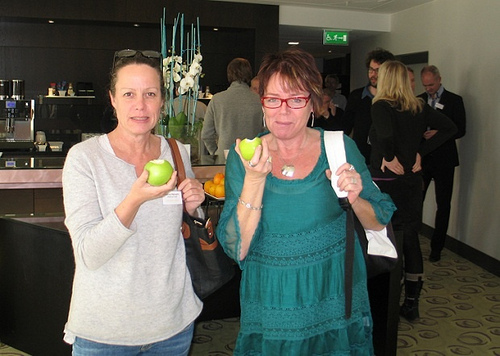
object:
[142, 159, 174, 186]
apples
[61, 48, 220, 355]
lady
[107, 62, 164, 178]
light skin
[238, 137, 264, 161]
apple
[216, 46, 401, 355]
woman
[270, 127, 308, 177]
necklace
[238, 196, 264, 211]
wristband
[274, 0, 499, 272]
wall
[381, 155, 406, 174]
hands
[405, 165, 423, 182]
hips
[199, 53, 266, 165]
man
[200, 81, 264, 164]
sweater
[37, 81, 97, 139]
coffee maker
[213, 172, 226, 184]
oranges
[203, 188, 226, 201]
bowl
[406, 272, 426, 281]
socks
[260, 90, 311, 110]
glasses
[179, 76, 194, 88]
flowers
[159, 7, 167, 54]
sticks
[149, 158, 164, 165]
bites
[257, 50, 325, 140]
head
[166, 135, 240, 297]
bag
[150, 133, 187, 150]
shoulder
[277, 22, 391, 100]
hall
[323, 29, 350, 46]
sign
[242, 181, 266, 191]
wrist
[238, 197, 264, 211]
bracelet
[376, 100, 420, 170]
back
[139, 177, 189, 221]
chest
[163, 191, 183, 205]
tag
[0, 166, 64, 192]
counter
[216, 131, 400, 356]
dress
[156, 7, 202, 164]
floral arrangement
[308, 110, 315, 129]
earrings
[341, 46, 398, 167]
man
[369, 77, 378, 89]
beard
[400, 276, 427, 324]
boot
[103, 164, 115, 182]
white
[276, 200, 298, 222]
green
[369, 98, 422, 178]
suit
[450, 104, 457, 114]
black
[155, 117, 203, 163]
pot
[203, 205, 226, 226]
basket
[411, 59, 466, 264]
man